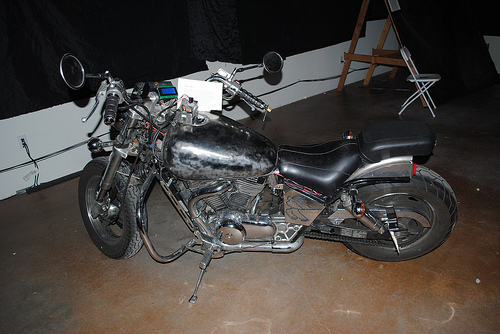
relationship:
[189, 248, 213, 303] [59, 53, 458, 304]
kick stand on bike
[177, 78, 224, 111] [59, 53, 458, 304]
paper on bike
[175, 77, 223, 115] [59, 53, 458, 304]
paper on bike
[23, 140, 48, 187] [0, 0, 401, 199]
cord plugged into a wall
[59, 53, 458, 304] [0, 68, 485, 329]
bike parked on floor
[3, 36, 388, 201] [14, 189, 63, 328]
panel across floor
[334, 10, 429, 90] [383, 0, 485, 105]
wooden support for wood surface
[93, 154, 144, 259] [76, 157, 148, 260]
dust on edge of tire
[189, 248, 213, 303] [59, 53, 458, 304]
kick stand for bike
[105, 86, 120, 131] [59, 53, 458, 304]
handle bar of bike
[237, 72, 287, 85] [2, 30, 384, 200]
shadow cast on wood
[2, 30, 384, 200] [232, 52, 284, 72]
wood by a mirror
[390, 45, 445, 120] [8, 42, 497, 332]
seat on floor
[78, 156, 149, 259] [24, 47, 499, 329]
tire on a bike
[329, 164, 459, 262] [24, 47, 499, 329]
back wheel on a bike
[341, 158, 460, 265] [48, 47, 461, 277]
back wheel on a bike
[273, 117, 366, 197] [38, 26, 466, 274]
seat on a bike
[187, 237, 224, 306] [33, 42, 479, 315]
kick stand on a bike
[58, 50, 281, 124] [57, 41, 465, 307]
handlebars on a bike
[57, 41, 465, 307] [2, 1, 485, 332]
bike in a room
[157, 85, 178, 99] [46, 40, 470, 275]
cellphone on motorcycle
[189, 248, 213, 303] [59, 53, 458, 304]
kick stand on a bike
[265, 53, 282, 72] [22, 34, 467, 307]
mirror on motorcycle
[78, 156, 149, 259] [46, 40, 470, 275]
tire on front of motorcycle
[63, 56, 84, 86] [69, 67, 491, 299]
mirror on motorcycle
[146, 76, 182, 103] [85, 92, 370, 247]
cellphone on motorcycle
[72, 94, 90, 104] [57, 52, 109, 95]
shadow cast by mirror